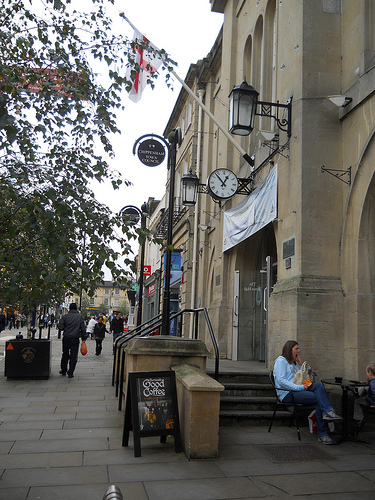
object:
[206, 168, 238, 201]
clock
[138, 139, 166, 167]
sign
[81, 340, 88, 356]
bag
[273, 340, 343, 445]
woman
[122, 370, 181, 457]
sign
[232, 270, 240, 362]
door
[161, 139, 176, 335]
pole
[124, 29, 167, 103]
flag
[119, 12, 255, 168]
pole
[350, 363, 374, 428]
boy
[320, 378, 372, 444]
table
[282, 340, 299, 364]
hair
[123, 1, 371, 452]
building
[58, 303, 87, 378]
person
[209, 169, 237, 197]
face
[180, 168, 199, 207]
light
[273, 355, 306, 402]
sweater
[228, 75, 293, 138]
lantern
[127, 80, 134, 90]
leaf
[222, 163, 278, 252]
banner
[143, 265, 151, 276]
sign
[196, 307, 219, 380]
handrail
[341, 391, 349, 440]
legs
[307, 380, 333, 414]
legs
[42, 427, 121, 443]
blocks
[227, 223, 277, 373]
entrance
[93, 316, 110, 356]
person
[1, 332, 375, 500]
sidewalk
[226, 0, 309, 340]
wall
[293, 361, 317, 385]
purse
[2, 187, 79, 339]
tree